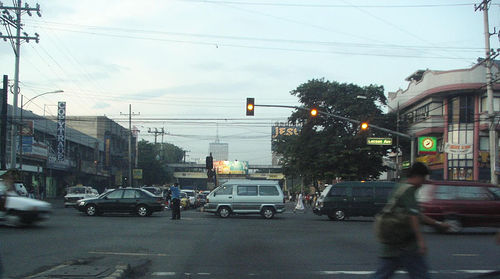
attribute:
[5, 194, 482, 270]
road — tarmacked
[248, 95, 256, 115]
traffic light — yellow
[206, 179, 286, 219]
van — silver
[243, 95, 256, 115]
light — yellow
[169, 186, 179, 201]
shirt — blue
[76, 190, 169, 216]
car — black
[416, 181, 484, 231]
car — blurred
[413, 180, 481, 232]
car — red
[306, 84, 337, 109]
leaves — green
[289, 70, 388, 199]
tree — well-grown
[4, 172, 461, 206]
traffic — busy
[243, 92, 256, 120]
streetlight — yellow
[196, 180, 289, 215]
compact van — old, small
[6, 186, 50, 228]
car — blurred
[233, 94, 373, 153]
lights — three yellow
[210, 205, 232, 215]
front tire — vehicle's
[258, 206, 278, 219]
rear tire — vehicle's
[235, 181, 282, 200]
windows — rear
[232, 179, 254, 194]
side window — vehicles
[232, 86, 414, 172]
traffic lights — three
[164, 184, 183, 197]
shirt — blue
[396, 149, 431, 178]
hat — black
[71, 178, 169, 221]
car — black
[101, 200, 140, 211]
doors — four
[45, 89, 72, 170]
sign — blue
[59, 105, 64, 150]
letters — white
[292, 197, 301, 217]
dress — white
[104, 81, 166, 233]
pole — wood 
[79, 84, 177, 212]
building — tall 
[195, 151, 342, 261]
van — mini , silver 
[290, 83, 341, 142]
light — yellow 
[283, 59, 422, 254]
tree — green 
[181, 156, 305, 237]
van — silver 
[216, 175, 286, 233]
van — green 